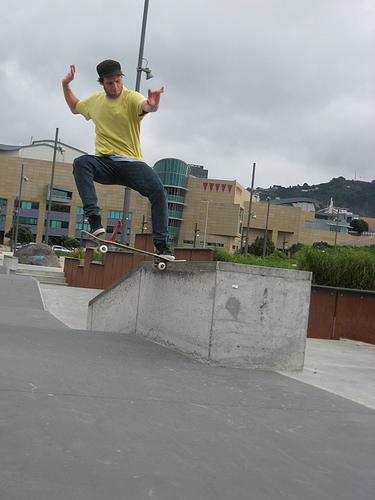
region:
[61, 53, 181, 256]
man in yellow shirt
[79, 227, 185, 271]
skateboard with white wheels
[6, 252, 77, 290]
three steps between walls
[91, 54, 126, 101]
head of man wearing dark cap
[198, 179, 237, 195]
five red triangles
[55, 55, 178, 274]
man with arms extended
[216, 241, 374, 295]
bushes with green foliage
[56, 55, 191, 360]
person doing trick on skateboard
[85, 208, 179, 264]
black high top sneakers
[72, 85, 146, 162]
yellow tee shirt on boy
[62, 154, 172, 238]
blue jeans on boy skating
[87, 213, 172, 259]
black hightops with white soles on them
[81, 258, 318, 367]
grey cement ramp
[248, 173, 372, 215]
green hills in background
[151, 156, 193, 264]
tall glass center in large building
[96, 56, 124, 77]
dark hat on skateboarder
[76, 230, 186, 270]
skateboard with white wheels in air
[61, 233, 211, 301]
brown wooden wall along skate park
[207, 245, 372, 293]
green vegetation in brown box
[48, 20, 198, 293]
the man is skateboarding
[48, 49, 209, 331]
the man is skateboarding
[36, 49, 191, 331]
the man is skateboarding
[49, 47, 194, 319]
the man is skateboarding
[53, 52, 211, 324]
the man is skateboarding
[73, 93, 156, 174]
the tee shirt is yellow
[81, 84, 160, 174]
the tee shirt is yellow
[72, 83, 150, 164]
the tee shirt is yellow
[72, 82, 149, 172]
the tee shirt is yellow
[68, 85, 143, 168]
the tee shirt is yellow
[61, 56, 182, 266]
Skateboarder doing tricks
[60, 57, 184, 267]
Skateboarder doing a trick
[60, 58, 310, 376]
Skateboarder grinding concrete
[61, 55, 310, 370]
Skateboarder grinding concrete wearing a black hat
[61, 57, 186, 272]
Skateboarder grinding wearing a black hat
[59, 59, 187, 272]
Skateboarder grinding wearing a yellow t-shirt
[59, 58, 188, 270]
Skateboarder grinding wearing a black hat and a yellow t-shirt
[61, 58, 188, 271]
Skateboarder doing a trick wearing jeans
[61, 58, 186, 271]
Caucasian skateboarder grinding a block of concrete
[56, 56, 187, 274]
White skater doing a grind trick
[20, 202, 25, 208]
glass window on building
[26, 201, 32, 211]
glass window on building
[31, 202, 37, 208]
glass window on building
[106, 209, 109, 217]
glass window on building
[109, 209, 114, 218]
glass window on building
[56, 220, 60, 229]
glass window on building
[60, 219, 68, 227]
glass window on building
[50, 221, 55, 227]
glass window on building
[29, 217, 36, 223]
glass window on building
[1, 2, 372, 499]
Skateboarder, near ramp, at skate park, backed by commercial buildings.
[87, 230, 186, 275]
Skateboard, on edge of ramp.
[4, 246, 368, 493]
Grey skating area with ramp and bordering, brick wall.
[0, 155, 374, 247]
Modern, blue and tan buildings, beyond skating area.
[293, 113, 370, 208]
Vista of grey, cloudy sky and distant, green hills.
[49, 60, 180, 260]
man on top of skateboard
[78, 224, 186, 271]
man's skateboard in air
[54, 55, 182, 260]
man doing tricks on skateboard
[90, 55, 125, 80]
man's cap is brown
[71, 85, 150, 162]
man wearing yellow shirt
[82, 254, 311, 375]
railing wall by path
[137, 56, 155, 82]
light hanging off pole